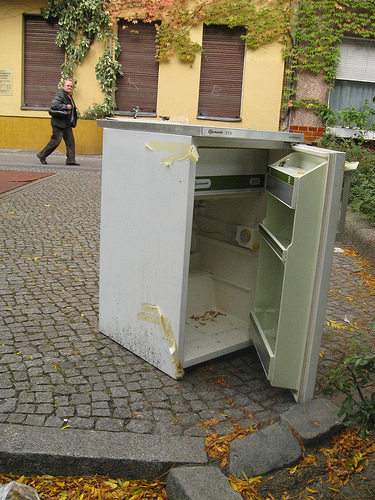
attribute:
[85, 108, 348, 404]
freezer — black, white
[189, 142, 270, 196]
freezer — black, white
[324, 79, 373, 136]
curtain — white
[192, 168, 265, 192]
freezer part — black and white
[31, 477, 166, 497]
leaves — orange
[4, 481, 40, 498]
plastic bag — clear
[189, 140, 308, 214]
freezer — white, black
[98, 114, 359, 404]
freezer — black, white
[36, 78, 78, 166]
person — walking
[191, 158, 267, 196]
freezer — white, black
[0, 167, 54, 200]
outdoor carpet — red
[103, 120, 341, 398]
refrigerator — white, open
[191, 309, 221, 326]
bits — orange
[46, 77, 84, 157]
lady — walking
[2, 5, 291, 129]
stucco — yellow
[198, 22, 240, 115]
shades — brown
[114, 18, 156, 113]
shades — brown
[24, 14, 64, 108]
shades — brown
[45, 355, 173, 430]
stone — grey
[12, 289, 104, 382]
pavers — brick